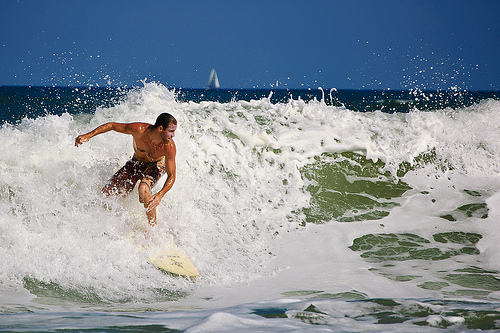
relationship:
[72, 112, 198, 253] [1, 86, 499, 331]
man in water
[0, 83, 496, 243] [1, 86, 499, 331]
wave in water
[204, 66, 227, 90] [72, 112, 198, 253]
sailboat behind man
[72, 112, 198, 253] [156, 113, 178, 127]
man has hair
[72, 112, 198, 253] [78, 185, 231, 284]
man on surfboard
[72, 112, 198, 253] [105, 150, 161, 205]
man wearing shorts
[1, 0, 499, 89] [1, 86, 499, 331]
sky above water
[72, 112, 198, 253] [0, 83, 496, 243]
man on wave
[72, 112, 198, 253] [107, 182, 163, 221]
man has bare legs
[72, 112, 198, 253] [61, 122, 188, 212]
man extending arms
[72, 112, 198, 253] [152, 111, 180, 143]
man has head